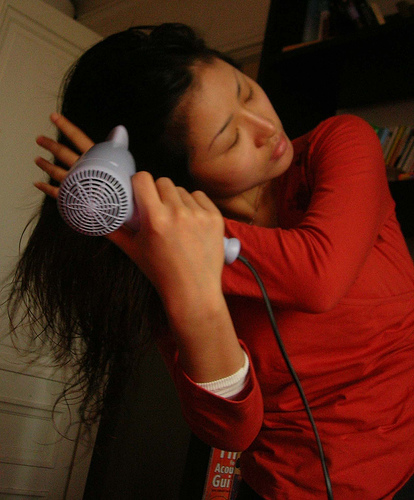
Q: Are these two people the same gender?
A: Yes, all the people are female.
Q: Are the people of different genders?
A: No, all the people are female.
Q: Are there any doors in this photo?
A: Yes, there is a door.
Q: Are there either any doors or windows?
A: Yes, there is a door.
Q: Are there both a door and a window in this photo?
A: No, there is a door but no windows.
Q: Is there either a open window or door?
A: Yes, there is an open door.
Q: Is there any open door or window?
A: Yes, there is an open door.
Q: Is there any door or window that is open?
A: Yes, the door is open.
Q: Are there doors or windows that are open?
A: Yes, the door is open.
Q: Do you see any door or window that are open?
A: Yes, the door is open.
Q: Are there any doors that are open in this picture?
A: Yes, there is an open door.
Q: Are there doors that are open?
A: Yes, there is a door that is open.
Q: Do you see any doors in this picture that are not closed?
A: Yes, there is a open door.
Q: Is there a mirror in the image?
A: No, there are no mirrors.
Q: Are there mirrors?
A: No, there are no mirrors.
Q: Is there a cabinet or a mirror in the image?
A: No, there are no mirrors or cabinets.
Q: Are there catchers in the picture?
A: No, there are no catchers.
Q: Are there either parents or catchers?
A: No, there are no catchers or parents.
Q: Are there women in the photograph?
A: Yes, there is a woman.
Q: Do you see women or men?
A: Yes, there is a woman.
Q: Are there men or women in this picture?
A: Yes, there is a woman.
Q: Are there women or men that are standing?
A: Yes, the woman is standing.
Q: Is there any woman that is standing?
A: Yes, there is a woman that is standing.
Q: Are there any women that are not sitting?
A: Yes, there is a woman that is standing.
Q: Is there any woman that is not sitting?
A: Yes, there is a woman that is standing.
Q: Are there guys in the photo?
A: No, there are no guys.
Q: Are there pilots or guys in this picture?
A: No, there are no guys or pilots.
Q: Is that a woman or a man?
A: That is a woman.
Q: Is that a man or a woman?
A: That is a woman.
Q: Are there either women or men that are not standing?
A: No, there is a woman but she is standing.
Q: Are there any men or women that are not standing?
A: No, there is a woman but she is standing.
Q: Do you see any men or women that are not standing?
A: No, there is a woman but she is standing.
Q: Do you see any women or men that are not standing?
A: No, there is a woman but she is standing.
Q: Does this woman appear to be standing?
A: Yes, the woman is standing.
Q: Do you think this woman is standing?
A: Yes, the woman is standing.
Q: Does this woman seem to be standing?
A: Yes, the woman is standing.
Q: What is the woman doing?
A: The woman is standing.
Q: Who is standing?
A: The woman is standing.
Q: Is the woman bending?
A: No, the woman is standing.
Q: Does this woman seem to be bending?
A: No, the woman is standing.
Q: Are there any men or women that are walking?
A: No, there is a woman but she is standing.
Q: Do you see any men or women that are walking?
A: No, there is a woman but she is standing.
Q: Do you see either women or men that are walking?
A: No, there is a woman but she is standing.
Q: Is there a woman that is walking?
A: No, there is a woman but she is standing.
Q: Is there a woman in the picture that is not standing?
A: No, there is a woman but she is standing.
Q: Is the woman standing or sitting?
A: The woman is standing.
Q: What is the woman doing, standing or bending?
A: The woman is standing.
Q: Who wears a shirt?
A: The woman wears a shirt.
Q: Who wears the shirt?
A: The woman wears a shirt.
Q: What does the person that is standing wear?
A: The woman wears a shirt.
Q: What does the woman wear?
A: The woman wears a shirt.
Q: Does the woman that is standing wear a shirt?
A: Yes, the woman wears a shirt.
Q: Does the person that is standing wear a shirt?
A: Yes, the woman wears a shirt.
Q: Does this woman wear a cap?
A: No, the woman wears a shirt.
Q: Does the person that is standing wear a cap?
A: No, the woman wears a shirt.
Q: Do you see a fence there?
A: No, there are no fences.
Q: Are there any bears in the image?
A: No, there are no bears.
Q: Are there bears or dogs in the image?
A: No, there are no bears or dogs.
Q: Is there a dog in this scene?
A: No, there are no dogs.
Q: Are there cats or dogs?
A: No, there are no dogs or cats.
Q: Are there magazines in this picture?
A: No, there are no magazines.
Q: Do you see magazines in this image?
A: No, there are no magazines.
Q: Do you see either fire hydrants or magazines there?
A: No, there are no magazines or fire hydrants.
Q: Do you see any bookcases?
A: Yes, there is a bookcase.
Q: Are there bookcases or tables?
A: Yes, there is a bookcase.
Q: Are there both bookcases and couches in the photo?
A: No, there is a bookcase but no couches.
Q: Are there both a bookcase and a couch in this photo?
A: No, there is a bookcase but no couches.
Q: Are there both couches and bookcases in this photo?
A: No, there is a bookcase but no couches.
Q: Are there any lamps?
A: No, there are no lamps.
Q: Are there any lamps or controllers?
A: No, there are no lamps or controllers.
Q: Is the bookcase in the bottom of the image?
A: Yes, the bookcase is in the bottom of the image.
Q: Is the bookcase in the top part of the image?
A: No, the bookcase is in the bottom of the image.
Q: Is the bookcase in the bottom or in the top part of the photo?
A: The bookcase is in the bottom of the image.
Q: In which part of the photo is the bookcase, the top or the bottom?
A: The bookcase is in the bottom of the image.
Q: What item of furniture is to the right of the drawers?
A: The piece of furniture is a bookcase.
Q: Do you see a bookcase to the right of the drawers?
A: Yes, there is a bookcase to the right of the drawers.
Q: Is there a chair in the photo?
A: No, there are no chairs.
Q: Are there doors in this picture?
A: Yes, there is a door.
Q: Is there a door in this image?
A: Yes, there is a door.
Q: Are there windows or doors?
A: Yes, there is a door.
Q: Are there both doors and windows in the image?
A: No, there is a door but no windows.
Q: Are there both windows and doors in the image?
A: No, there is a door but no windows.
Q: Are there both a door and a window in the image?
A: No, there is a door but no windows.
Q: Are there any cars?
A: No, there are no cars.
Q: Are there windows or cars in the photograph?
A: No, there are no cars or windows.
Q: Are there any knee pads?
A: No, there are no knee pads.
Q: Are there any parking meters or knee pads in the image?
A: No, there are no knee pads or parking meters.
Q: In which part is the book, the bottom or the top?
A: The book is in the bottom of the image.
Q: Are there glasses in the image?
A: No, there are no glasses.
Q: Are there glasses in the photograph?
A: No, there are no glasses.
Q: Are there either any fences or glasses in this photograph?
A: No, there are no glasses or fences.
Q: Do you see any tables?
A: No, there are no tables.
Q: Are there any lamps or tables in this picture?
A: No, there are no tables or lamps.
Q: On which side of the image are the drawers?
A: The drawers are on the left of the image.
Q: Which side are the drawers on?
A: The drawers are on the left of the image.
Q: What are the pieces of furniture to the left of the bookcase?
A: The pieces of furniture are drawers.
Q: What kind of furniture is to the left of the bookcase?
A: The pieces of furniture are drawers.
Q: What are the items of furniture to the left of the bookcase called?
A: The pieces of furniture are drawers.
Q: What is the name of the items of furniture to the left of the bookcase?
A: The pieces of furniture are drawers.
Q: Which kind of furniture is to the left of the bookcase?
A: The pieces of furniture are drawers.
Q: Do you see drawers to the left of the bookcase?
A: Yes, there are drawers to the left of the bookcase.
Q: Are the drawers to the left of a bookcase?
A: Yes, the drawers are to the left of a bookcase.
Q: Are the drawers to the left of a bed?
A: No, the drawers are to the left of a bookcase.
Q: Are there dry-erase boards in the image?
A: No, there are no dry-erase boards.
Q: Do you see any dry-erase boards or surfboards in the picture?
A: No, there are no dry-erase boards or surfboards.